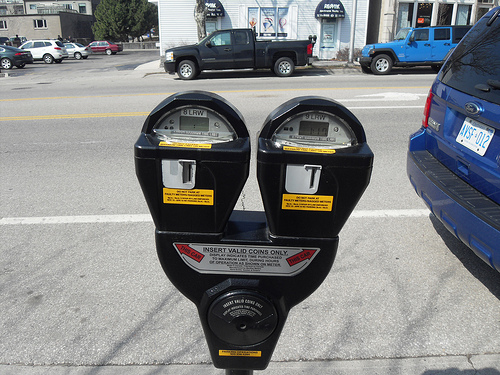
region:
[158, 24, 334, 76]
black truck parked across street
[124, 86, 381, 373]
parking meter at side of street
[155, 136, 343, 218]
yellow information stickers at top of meter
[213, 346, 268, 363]
yellow information sticker at bottom of meter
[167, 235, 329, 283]
red and white sticker at center of meter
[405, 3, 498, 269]
blue ford parker near meter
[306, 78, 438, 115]
white arrow painted on road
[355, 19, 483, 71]
light blue car parked across street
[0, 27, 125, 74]
cars parked in a lot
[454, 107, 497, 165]
license plate on blue ford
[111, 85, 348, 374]
double parking meter by street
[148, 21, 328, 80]
black pick-up truck parked by street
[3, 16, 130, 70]
four vehicles in parking lot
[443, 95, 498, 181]
license tag on blue vehicle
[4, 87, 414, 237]
yellow and white lines on street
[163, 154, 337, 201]
coin slots on parking meter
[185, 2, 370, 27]
awnings over doors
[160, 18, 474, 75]
blue jeep behind black truck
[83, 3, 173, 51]
tree behind parking lot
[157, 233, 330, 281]
red arrow indicators on meter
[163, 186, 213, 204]
yellow rectangle sticker with black writing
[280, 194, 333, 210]
yellow rectangle sticker with black writing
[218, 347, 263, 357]
yellow rectangle sticker with black writing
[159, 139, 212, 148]
yellow rectangle sticker with black writing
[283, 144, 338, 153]
yellow rectangle sticker with black writing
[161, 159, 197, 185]
metal coin slot on parking meter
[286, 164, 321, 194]
metal coin slot on parking meter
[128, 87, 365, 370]
black yellow grey and red parking meter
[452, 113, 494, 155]
blue and white license plate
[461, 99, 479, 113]
blue and silver Ford symbol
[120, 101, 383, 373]
The meter is black.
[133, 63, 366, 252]
Two meters on one stand.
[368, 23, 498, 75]
A blue jeep is parked across the street.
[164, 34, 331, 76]
A black truck is parked across the street.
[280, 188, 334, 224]
The meter has a yellow sticker on it.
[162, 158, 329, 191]
The coin slot on the parking meters is silver.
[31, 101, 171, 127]
The street has a yellow line in the middle.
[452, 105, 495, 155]
The car tag has blue numbers.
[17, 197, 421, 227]
A white line is in the street.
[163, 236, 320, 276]
The meter has red arrows pointing upward.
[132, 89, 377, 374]
parking meter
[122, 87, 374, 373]
double parking meter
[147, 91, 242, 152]
parking meter face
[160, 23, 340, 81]
black truck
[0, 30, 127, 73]
parked cars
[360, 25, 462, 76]
blue jeep parked on street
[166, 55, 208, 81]
black truck tire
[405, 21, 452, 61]
door on blue jeep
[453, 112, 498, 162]
license plate on truck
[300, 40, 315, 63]
rear light on truck